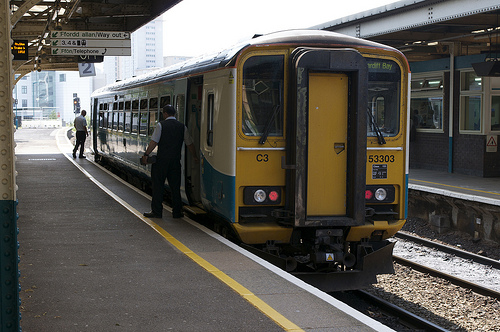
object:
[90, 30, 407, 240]
train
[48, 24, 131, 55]
sign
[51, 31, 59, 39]
arrows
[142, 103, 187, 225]
man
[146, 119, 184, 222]
uniform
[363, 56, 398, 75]
destination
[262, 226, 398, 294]
bumper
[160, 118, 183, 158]
shirt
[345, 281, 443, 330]
tracks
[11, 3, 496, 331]
platform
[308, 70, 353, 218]
door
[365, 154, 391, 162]
number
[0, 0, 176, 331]
building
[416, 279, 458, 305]
gravel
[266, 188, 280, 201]
light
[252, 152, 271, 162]
sign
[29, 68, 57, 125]
building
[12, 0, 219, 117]
background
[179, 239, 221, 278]
line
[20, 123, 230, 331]
pavemenet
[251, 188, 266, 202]
headlight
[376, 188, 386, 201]
headlight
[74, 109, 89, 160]
man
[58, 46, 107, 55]
location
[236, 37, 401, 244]
front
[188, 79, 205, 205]
door